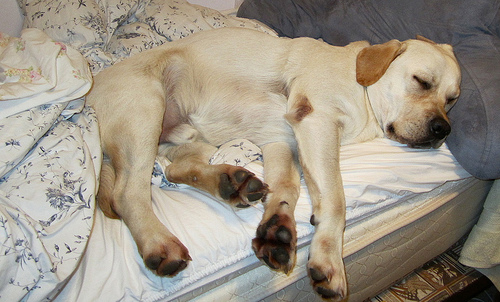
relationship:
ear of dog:
[357, 43, 405, 82] [72, 36, 496, 268]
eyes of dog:
[413, 70, 457, 106] [72, 36, 496, 268]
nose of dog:
[430, 119, 451, 136] [72, 36, 496, 268]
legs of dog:
[99, 139, 350, 264] [72, 36, 496, 268]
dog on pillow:
[72, 36, 496, 268] [376, 3, 499, 151]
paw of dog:
[255, 216, 299, 267] [72, 36, 496, 268]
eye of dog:
[415, 76, 432, 90] [72, 36, 496, 268]